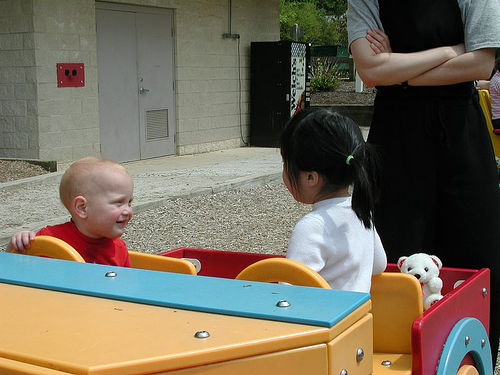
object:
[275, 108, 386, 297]
children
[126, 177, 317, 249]
gravel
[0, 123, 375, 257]
ground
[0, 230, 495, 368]
train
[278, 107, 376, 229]
hair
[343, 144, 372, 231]
ponytail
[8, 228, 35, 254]
hands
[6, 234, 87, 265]
seat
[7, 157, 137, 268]
children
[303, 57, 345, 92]
bush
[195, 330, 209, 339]
bolt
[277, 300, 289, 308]
bolt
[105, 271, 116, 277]
bolt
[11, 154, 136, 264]
boy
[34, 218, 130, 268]
red shirt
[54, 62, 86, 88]
plate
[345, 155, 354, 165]
band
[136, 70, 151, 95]
handle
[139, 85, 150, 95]
lock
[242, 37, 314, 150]
machine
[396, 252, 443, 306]
stuffed animal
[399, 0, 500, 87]
arms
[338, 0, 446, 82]
arms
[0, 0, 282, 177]
building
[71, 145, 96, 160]
cement blocks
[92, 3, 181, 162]
doors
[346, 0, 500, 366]
person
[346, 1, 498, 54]
shirt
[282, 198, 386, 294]
shirt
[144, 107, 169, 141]
vent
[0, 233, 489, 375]
car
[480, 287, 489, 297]
silver button